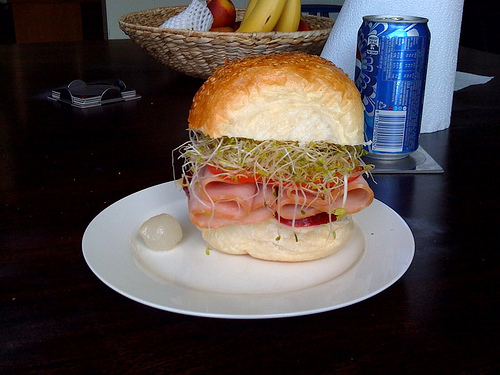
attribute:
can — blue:
[349, 8, 426, 158]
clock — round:
[60, 265, 400, 334]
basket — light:
[112, 7, 341, 62]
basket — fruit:
[117, 0, 346, 72]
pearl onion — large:
[134, 215, 183, 247]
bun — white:
[196, 55, 361, 140]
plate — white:
[80, 175, 415, 317]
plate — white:
[89, 171, 407, 362]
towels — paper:
[328, 13, 480, 131]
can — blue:
[344, 5, 438, 174]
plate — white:
[75, 174, 422, 330]